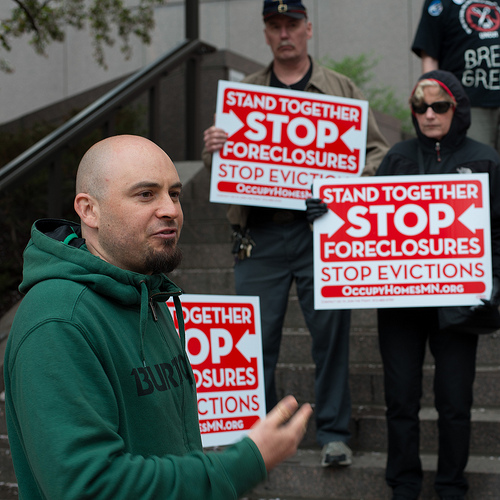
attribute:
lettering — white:
[320, 187, 483, 297]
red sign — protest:
[210, 78, 369, 210]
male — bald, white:
[5, 120, 330, 499]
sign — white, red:
[206, 76, 370, 216]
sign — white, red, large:
[166, 288, 270, 449]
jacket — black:
[371, 136, 498, 336]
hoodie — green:
[0, 218, 267, 498]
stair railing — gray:
[106, 35, 193, 95]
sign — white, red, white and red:
[311, 173, 491, 309]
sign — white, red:
[155, 294, 265, 451]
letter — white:
[346, 203, 371, 237]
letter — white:
[368, 203, 395, 236]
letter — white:
[394, 204, 426, 235]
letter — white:
[427, 203, 454, 235]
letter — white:
[243, 110, 268, 142]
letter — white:
[264, 112, 287, 143]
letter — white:
[287, 117, 315, 147]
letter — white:
[316, 119, 338, 149]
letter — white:
[209, 327, 234, 364]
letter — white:
[178, 327, 212, 364]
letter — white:
[322, 183, 334, 205]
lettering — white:
[343, 200, 455, 237]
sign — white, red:
[205, 80, 367, 205]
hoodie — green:
[16, 222, 233, 489]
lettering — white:
[221, 135, 362, 175]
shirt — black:
[408, 0, 499, 112]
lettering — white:
[324, 237, 481, 257]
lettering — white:
[188, 306, 250, 325]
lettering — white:
[223, 139, 360, 172]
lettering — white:
[344, 205, 454, 238]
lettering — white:
[320, 187, 382, 202]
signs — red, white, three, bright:
[203, 76, 361, 196]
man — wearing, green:
[1, 102, 277, 411]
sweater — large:
[39, 269, 169, 409]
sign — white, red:
[263, 172, 456, 292]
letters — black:
[132, 362, 201, 397]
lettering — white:
[319, 185, 484, 254]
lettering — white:
[322, 181, 482, 258]